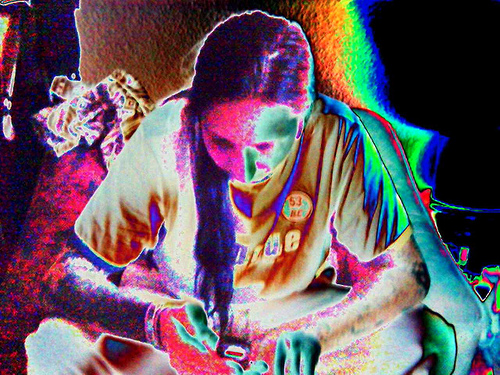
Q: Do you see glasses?
A: No, there are no glasses.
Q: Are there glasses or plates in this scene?
A: No, there are no glasses or plates.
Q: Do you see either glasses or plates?
A: No, there are no glasses or plates.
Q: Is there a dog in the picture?
A: No, there are no dogs.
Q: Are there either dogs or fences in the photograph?
A: No, there are no dogs or fences.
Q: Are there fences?
A: No, there are no fences.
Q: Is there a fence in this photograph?
A: No, there are no fences.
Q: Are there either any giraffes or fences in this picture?
A: No, there are no fences or giraffes.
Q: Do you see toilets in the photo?
A: No, there are no toilets.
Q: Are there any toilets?
A: No, there are no toilets.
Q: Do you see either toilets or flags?
A: No, there are no toilets or flags.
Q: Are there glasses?
A: No, there are no glasses.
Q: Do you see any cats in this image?
A: No, there are no cats.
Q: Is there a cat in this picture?
A: No, there are no cats.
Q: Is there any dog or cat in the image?
A: No, there are no cats or dogs.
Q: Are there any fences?
A: No, there are no fences.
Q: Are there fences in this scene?
A: No, there are no fences.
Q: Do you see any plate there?
A: No, there are no plates.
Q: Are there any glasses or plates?
A: No, there are no plates or glasses.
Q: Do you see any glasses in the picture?
A: No, there are no glasses.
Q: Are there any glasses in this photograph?
A: No, there are no glasses.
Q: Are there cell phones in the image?
A: Yes, there is a cell phone.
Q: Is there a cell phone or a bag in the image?
A: Yes, there is a cell phone.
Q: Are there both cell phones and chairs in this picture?
A: Yes, there are both a cell phone and a chair.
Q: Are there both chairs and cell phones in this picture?
A: Yes, there are both a cell phone and a chair.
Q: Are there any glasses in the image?
A: No, there are no glasses.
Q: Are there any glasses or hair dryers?
A: No, there are no glasses or hair dryers.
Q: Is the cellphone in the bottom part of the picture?
A: Yes, the cellphone is in the bottom of the image.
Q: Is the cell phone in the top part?
A: No, the cell phone is in the bottom of the image.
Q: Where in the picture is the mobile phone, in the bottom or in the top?
A: The mobile phone is in the bottom of the image.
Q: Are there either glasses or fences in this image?
A: No, there are no fences or glasses.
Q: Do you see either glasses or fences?
A: No, there are no fences or glasses.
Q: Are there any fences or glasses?
A: No, there are no fences or glasses.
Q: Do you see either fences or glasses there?
A: No, there are no fences or glasses.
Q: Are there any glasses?
A: No, there are no glasses.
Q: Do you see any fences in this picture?
A: No, there are no fences.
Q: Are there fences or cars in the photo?
A: No, there are no fences or cars.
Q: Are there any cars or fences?
A: No, there are no fences or cars.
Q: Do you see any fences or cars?
A: No, there are no fences or cars.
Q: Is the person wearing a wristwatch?
A: Yes, the person is wearing a wristwatch.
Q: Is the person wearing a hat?
A: No, the person is wearing a wristwatch.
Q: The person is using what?
A: The person is using a cellphone.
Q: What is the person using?
A: The person is using a cellphone.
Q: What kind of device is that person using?
A: The person is using a cell phone.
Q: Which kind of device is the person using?
A: The person is using a cell phone.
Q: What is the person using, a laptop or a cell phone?
A: The person is using a cell phone.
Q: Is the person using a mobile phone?
A: Yes, the person is using a mobile phone.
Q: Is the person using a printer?
A: No, the person is using a mobile phone.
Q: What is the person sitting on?
A: The person is sitting on the chair.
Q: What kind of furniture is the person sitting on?
A: The person is sitting on the chair.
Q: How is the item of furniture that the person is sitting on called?
A: The piece of furniture is a chair.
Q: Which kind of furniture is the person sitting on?
A: The person is sitting on the chair.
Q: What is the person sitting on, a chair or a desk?
A: The person is sitting on a chair.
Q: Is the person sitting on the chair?
A: Yes, the person is sitting on the chair.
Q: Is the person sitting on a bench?
A: No, the person is sitting on the chair.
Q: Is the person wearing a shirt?
A: Yes, the person is wearing a shirt.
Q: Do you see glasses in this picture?
A: No, there are no glasses.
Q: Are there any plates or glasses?
A: No, there are no glasses or plates.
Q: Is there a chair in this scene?
A: Yes, there is a chair.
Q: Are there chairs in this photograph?
A: Yes, there is a chair.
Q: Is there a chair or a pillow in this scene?
A: Yes, there is a chair.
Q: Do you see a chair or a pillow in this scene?
A: Yes, there is a chair.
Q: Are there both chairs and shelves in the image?
A: No, there is a chair but no shelves.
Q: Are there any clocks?
A: No, there are no clocks.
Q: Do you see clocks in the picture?
A: No, there are no clocks.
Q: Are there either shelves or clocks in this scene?
A: No, there are no clocks or shelves.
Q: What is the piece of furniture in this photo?
A: The piece of furniture is a chair.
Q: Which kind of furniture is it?
A: The piece of furniture is a chair.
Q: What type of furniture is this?
A: This is a chair.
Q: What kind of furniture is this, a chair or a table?
A: This is a chair.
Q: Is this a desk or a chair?
A: This is a chair.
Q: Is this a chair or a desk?
A: This is a chair.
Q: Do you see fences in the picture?
A: No, there are no fences.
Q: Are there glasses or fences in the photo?
A: No, there are no fences or glasses.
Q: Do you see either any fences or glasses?
A: No, there are no fences or glasses.